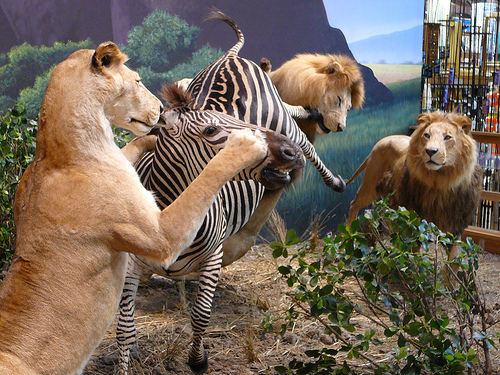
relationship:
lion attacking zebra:
[209, 45, 366, 244] [113, 5, 350, 372]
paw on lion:
[224, 126, 264, 170] [1, 37, 267, 372]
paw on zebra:
[224, 126, 264, 170] [98, 7, 363, 374]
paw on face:
[224, 126, 264, 170] [153, 87, 305, 192]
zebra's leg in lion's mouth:
[278, 102, 313, 123] [304, 96, 333, 145]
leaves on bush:
[283, 200, 495, 373] [244, 195, 497, 371]